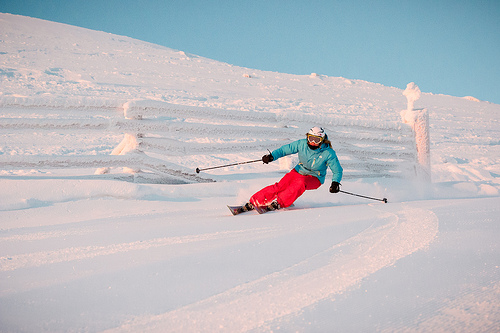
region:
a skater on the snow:
[214, 116, 352, 226]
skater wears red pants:
[222, 119, 353, 221]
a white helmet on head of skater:
[291, 116, 339, 163]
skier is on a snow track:
[34, 106, 444, 324]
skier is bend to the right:
[218, 119, 350, 226]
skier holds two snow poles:
[188, 111, 402, 226]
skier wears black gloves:
[218, 118, 353, 222]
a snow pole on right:
[337, 185, 397, 213]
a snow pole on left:
[188, 151, 259, 182]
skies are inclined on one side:
[218, 201, 299, 219]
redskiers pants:
[251, 175, 317, 200]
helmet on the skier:
[300, 115, 325, 130]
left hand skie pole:
[330, 180, 390, 200]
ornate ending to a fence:
[400, 80, 420, 130]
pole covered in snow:
[410, 120, 440, 175]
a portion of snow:
[5, 45, 105, 120]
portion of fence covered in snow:
[20, 100, 250, 185]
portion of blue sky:
[270, 10, 490, 70]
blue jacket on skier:
[304, 150, 345, 177]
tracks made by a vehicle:
[205, 210, 446, 331]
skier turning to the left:
[171, 118, 398, 230]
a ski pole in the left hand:
[323, 184, 403, 206]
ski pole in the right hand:
[181, 146, 276, 181]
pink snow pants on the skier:
[232, 168, 322, 222]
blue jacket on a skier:
[270, 138, 355, 180]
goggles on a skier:
[302, 122, 336, 152]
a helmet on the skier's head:
[296, 115, 332, 158]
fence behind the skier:
[125, 98, 439, 186]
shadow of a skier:
[291, 185, 437, 215]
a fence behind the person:
[0, 91, 442, 185]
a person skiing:
[171, 98, 408, 235]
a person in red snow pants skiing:
[193, 100, 424, 242]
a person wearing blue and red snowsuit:
[191, 115, 401, 253]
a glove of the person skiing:
[328, 182, 340, 193]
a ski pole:
[338, 188, 393, 203]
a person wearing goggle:
[286, 119, 336, 164]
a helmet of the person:
[304, 125, 326, 137]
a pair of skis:
[222, 200, 270, 217]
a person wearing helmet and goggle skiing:
[213, 110, 368, 245]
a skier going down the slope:
[169, 103, 391, 231]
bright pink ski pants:
[242, 162, 327, 215]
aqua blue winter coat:
[265, 135, 347, 194]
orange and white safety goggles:
[302, 131, 327, 151]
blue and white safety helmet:
[306, 123, 326, 145]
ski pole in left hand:
[329, 183, 390, 210]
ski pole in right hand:
[189, 153, 277, 184]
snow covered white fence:
[9, 80, 447, 195]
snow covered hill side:
[5, 6, 495, 138]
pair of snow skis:
[224, 195, 299, 226]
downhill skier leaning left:
[185, 123, 400, 233]